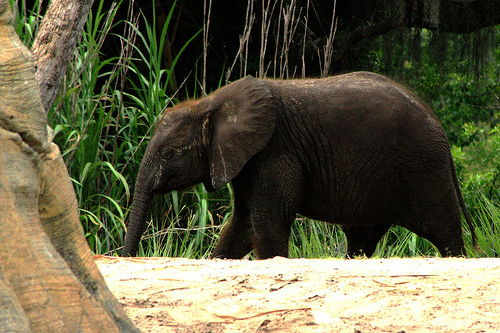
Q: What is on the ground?
A: Sand and leaves.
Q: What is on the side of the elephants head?
A: A gray ear.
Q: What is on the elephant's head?
A: A long trunk.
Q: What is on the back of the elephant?
A: Dark wrinkles.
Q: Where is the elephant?
A: Walking in a woody sandy area.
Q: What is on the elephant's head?
A: Ears.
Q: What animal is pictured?
A: Elephant.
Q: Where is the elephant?
A: Jungle.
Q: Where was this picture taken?
A: Jungle.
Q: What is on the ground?
A: Dirt.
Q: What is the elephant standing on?
A: Dirt.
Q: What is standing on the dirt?
A: Elephant.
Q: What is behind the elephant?
A: Grass.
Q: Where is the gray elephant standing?
A: Near trees in background.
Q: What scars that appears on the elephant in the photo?
A: Near is eyes.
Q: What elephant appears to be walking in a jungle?
A: The small elephant.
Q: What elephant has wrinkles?
A: Animal near green background.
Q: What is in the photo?
A: An animal.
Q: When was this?
A: Daytime.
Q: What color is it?
A: Grey.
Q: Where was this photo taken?
A: In a field.